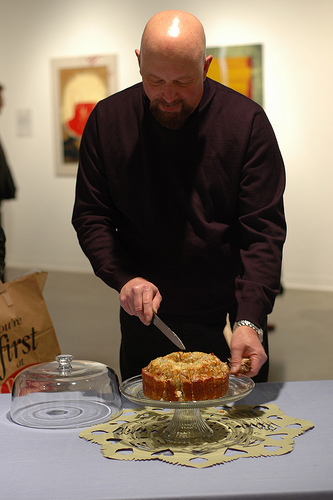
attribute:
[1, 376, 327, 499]
table — here, long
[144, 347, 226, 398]
cake — here, dark tan, sliced, brown, cut, small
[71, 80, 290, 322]
shirt — here, black, long sleeve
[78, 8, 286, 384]
man — here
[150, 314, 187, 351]
knife — here, pointy, stainless steel, sharp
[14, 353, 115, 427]
glass — here, clear, lid, cake cover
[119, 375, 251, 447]
dish — glass, cake platter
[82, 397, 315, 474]
place mat — tan, decorative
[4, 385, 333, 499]
tablecloth — white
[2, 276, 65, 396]
shopping bag — brown, paper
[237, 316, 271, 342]
watch — metal, silver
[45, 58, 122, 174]
painting — blurred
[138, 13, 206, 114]
head — bald, shiny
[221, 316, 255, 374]
napkin — crumpled, brown